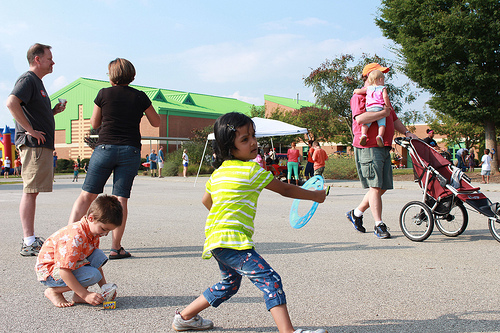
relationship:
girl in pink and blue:
[351, 67, 397, 150] [363, 81, 391, 127]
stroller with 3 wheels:
[393, 132, 499, 250] [394, 196, 499, 244]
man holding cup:
[3, 34, 73, 258] [54, 97, 69, 112]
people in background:
[266, 145, 335, 178] [249, 139, 357, 163]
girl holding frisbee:
[166, 109, 329, 333] [285, 167, 328, 231]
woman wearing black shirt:
[68, 54, 166, 207] [92, 84, 152, 148]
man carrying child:
[344, 56, 415, 240] [351, 67, 397, 150]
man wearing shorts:
[3, 34, 73, 258] [20, 144, 56, 193]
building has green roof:
[137, 83, 330, 133] [144, 88, 317, 111]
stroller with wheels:
[393, 132, 499, 250] [394, 196, 499, 244]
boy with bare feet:
[30, 189, 124, 316] [42, 289, 101, 307]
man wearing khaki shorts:
[3, 34, 73, 258] [20, 144, 56, 193]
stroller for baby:
[393, 132, 499, 250] [351, 67, 397, 150]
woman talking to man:
[68, 54, 166, 207] [3, 34, 73, 258]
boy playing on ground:
[30, 189, 124, 316] [0, 298, 161, 326]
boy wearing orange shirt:
[30, 189, 124, 316] [28, 216, 106, 277]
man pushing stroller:
[344, 56, 415, 240] [393, 132, 499, 250]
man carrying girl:
[344, 56, 415, 240] [351, 67, 397, 150]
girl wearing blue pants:
[351, 67, 397, 150] [363, 106, 388, 128]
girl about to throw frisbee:
[166, 109, 329, 333] [285, 167, 328, 231]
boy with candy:
[30, 189, 124, 316] [96, 278, 120, 309]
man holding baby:
[344, 56, 415, 240] [351, 67, 397, 150]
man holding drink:
[3, 34, 73, 258] [54, 97, 69, 112]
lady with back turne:
[68, 54, 166, 207] [92, 84, 152, 148]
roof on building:
[144, 88, 317, 111] [31, 73, 345, 183]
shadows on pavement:
[275, 234, 491, 330] [316, 241, 394, 331]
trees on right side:
[407, 6, 500, 134] [365, 1, 474, 322]